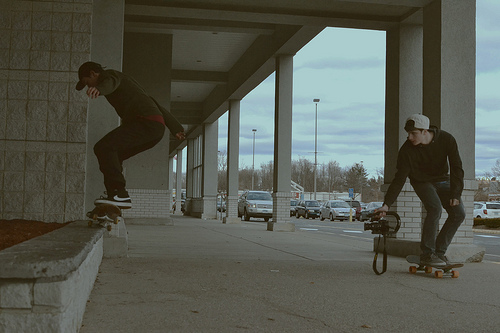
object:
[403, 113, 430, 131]
white hat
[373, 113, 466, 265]
boy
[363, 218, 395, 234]
camera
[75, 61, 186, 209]
skater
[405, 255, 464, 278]
skateboard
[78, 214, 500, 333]
sidewalk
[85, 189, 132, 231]
trick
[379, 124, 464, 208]
sweatshirt